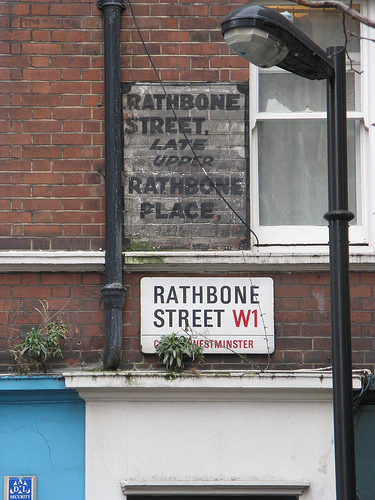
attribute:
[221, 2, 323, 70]
pails — Black , metal 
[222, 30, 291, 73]
glass — White 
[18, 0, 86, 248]
bricks — Red 